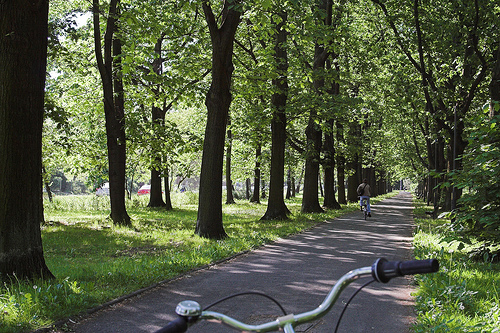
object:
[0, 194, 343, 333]
grass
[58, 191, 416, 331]
path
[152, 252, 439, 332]
bike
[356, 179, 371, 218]
person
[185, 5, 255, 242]
trees